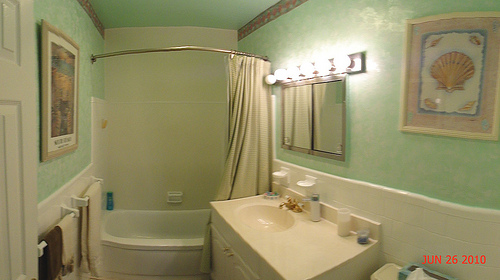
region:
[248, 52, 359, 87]
row of lights on the wall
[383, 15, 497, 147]
picture hanging on the wall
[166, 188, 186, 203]
soap dish hanging on the wall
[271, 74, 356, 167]
mirror on the wall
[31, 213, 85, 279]
two hand towels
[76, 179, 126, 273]
tan towel hanging on the wall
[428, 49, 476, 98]
drawing of a shell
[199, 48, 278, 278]
shower curtain pushed to one side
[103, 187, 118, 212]
blue bottle on the corner of the tub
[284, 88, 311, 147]
reflection in the mirror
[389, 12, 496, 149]
Picture on the wall.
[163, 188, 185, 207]
Soap holder on shower wall.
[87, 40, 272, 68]
Metal curtain rod.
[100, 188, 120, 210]
Blue shampoo bottle in tub.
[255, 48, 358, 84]
Light bulbs above the mirror.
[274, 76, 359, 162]
Mirror on the wall.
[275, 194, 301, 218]
Brass colored faucet on sink.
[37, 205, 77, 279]
towels hanging on the rod.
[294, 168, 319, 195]
white soap dish on wall.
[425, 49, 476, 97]
sea shell on picture.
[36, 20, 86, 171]
artwork on the wall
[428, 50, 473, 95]
picture of a shell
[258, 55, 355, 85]
row of lights above the mirror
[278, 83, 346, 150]
reflection in the mirror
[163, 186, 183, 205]
white soap dish on the wall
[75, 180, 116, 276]
tan towel hanging on the towel rod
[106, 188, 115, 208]
blue bottle on the corner of the tub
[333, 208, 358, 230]
cup on a sink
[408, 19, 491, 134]
picture of a seashell on the wall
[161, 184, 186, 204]
soap holder on the wall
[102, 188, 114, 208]
shampoo on the tub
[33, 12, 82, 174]
picture on the wall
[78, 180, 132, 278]
towels on a holder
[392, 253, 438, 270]
tissue in a box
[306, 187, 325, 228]
bottle on a sink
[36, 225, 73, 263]
bowl towel on a bar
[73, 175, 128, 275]
white towel on a bar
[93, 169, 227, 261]
a tub in a bathroom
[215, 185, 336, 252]
a sink in a bathroom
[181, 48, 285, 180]
a curtain in a bathroom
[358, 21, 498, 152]
a picture in a bathroom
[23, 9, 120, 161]
a picture on a wall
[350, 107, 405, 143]
a green painted wall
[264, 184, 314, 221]
the fossit on a seat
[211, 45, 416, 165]
a mirror in a bathroom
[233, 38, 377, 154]
the light in a bathroom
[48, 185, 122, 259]
towels in a bathroom